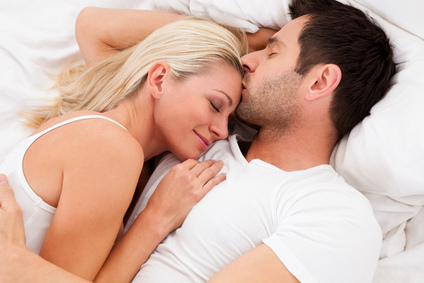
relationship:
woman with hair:
[1, 16, 247, 282] [16, 13, 246, 133]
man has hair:
[1, 1, 400, 283] [284, 0, 400, 149]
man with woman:
[1, 1, 400, 283] [1, 16, 247, 282]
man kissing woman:
[1, 1, 400, 283] [1, 16, 247, 282]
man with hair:
[1, 1, 400, 283] [284, 0, 400, 149]